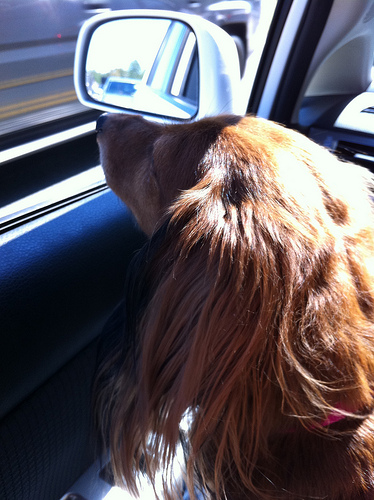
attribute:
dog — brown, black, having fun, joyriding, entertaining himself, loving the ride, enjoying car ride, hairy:
[92, 113, 373, 497]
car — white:
[2, 1, 373, 497]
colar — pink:
[270, 389, 373, 436]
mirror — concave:
[72, 8, 240, 128]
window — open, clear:
[2, 1, 280, 251]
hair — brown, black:
[98, 113, 373, 495]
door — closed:
[105, 24, 199, 120]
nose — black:
[95, 109, 109, 136]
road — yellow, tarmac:
[2, 53, 91, 142]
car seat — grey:
[56, 400, 211, 498]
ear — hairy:
[92, 195, 320, 473]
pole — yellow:
[6, 89, 78, 119]